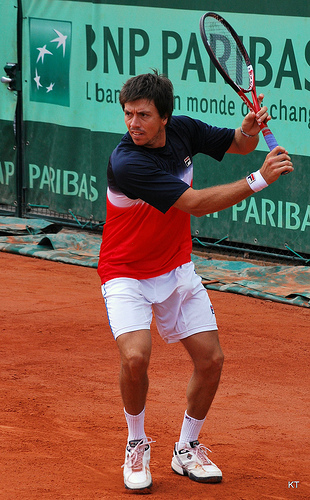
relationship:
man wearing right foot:
[107, 77, 296, 495] [119, 435, 157, 493]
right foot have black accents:
[119, 435, 157, 493] [125, 438, 202, 452]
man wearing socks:
[107, 77, 296, 495] [122, 412, 210, 452]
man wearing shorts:
[107, 77, 296, 495] [98, 258, 219, 337]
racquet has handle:
[192, 13, 292, 172] [258, 103, 281, 154]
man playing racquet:
[107, 77, 296, 495] [200, 12, 293, 176]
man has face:
[107, 77, 296, 495] [124, 83, 171, 143]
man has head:
[107, 77, 296, 495] [119, 69, 183, 148]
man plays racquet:
[107, 77, 296, 495] [200, 12, 293, 176]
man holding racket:
[107, 77, 296, 495] [192, 13, 292, 172]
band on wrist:
[246, 169, 267, 192] [231, 163, 270, 207]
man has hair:
[107, 77, 296, 495] [121, 68, 183, 118]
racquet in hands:
[192, 13, 292, 172] [244, 105, 296, 189]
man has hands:
[107, 77, 296, 495] [244, 105, 296, 189]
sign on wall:
[3, 4, 308, 244] [5, 0, 309, 267]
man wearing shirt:
[107, 77, 296, 495] [104, 115, 241, 283]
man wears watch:
[107, 77, 296, 495] [242, 123, 259, 144]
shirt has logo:
[104, 115, 241, 283] [184, 153, 196, 174]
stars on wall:
[32, 23, 68, 98] [5, 0, 309, 267]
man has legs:
[107, 77, 296, 495] [122, 316, 221, 436]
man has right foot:
[107, 77, 296, 495] [119, 439, 157, 492]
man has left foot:
[107, 77, 296, 495] [165, 437, 229, 483]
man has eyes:
[107, 77, 296, 495] [122, 101, 156, 124]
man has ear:
[107, 77, 296, 495] [161, 107, 178, 128]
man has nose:
[107, 77, 296, 495] [129, 112, 143, 131]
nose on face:
[129, 112, 143, 131] [124, 83, 171, 143]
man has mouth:
[107, 77, 296, 495] [122, 129, 149, 142]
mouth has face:
[122, 129, 149, 142] [124, 83, 171, 143]